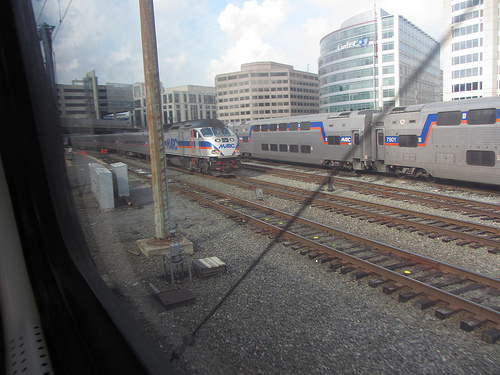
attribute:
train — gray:
[232, 94, 497, 191]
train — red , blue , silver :
[69, 119, 244, 177]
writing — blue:
[217, 141, 237, 150]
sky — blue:
[25, 0, 446, 92]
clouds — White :
[215, 1, 296, 61]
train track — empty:
[100, 152, 132, 169]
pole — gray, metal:
[137, 0, 170, 240]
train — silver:
[93, 112, 240, 182]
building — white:
[443, 1, 498, 108]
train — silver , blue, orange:
[228, 89, 498, 199]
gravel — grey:
[273, 281, 391, 367]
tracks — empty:
[233, 180, 494, 317]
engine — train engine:
[238, 92, 498, 194]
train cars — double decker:
[250, 100, 484, 200]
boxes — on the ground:
[87, 159, 133, 221]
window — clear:
[9, 0, 499, 364]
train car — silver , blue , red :
[93, 127, 116, 151]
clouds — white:
[37, 5, 459, 90]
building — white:
[51, 0, 482, 130]